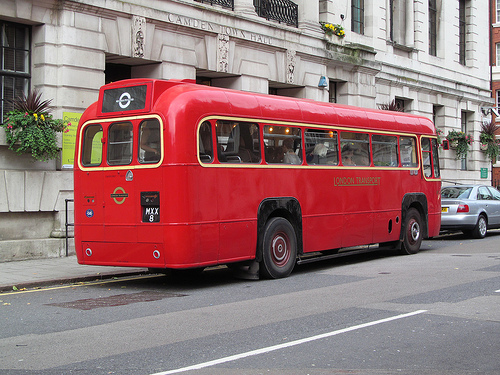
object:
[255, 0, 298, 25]
railing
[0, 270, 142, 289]
curb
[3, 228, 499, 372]
road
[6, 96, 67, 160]
flowers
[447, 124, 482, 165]
plants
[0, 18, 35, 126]
window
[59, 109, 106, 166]
sign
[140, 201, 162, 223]
white lettering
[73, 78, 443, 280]
bus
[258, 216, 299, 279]
tire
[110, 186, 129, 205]
logo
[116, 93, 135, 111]
sign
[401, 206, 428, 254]
tires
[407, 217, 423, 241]
caps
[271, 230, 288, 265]
caps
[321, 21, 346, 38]
flowers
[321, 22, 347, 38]
box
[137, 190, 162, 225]
tag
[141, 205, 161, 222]
"mxx 8"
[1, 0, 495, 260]
building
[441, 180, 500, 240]
automobile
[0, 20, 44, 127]
window box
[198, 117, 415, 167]
windows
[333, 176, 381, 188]
london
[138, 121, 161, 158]
person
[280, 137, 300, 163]
person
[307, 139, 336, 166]
person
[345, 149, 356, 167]
person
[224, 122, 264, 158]
person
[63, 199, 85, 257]
rail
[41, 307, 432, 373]
line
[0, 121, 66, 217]
sil